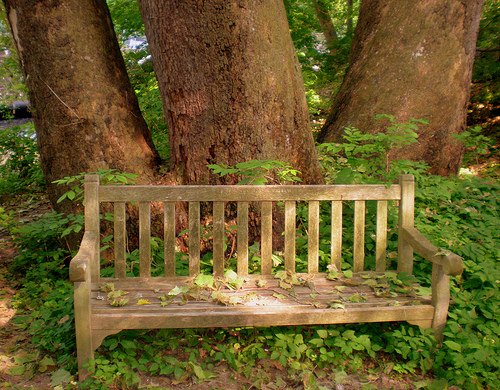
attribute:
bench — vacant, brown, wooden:
[71, 164, 452, 354]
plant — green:
[210, 335, 313, 372]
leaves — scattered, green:
[194, 269, 237, 306]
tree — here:
[3, 7, 168, 220]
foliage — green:
[434, 176, 498, 366]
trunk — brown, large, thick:
[145, 11, 324, 165]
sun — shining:
[455, 152, 484, 189]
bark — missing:
[132, 128, 160, 165]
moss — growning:
[442, 42, 463, 70]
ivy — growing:
[460, 193, 482, 359]